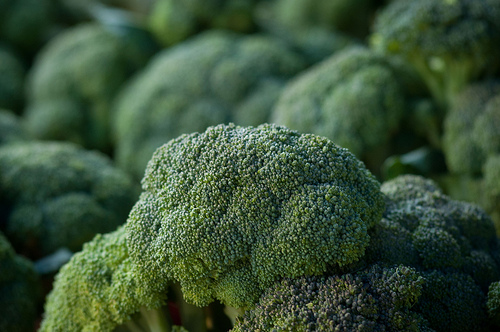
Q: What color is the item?
A: Green.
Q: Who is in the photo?
A: No one.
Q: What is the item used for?
A: Salad.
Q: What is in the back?
A: Broccoli.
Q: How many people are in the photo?
A: No one.